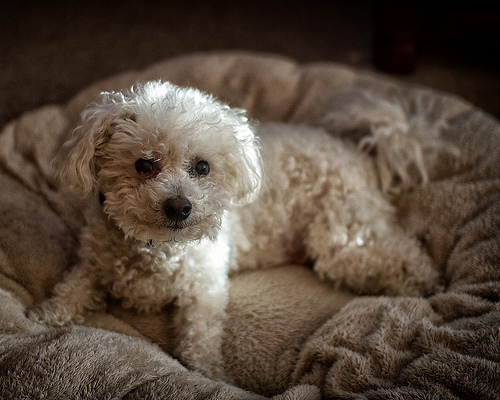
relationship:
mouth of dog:
[127, 176, 225, 226] [26, 79, 460, 384]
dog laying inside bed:
[17, 76, 459, 390] [0, 52, 499, 399]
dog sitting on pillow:
[17, 76, 459, 390] [1, 51, 498, 398]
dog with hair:
[17, 76, 459, 390] [71, 68, 431, 331]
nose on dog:
[161, 190, 198, 227] [17, 76, 459, 390]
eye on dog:
[188, 158, 212, 177] [8, 76, 299, 374]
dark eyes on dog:
[134, 158, 153, 174] [8, 76, 299, 374]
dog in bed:
[26, 79, 460, 384] [8, 52, 494, 389]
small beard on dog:
[141, 230, 210, 249] [26, 79, 460, 384]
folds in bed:
[303, 136, 467, 398] [8, 52, 494, 389]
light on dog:
[143, 78, 262, 290] [17, 76, 459, 390]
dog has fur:
[26, 79, 460, 384] [121, 93, 211, 130]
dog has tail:
[17, 76, 459, 390] [320, 81, 460, 189]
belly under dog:
[220, 238, 296, 278] [17, 76, 459, 390]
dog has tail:
[26, 79, 460, 384] [329, 91, 464, 200]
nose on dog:
[163, 195, 192, 220] [26, 79, 460, 384]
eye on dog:
[195, 160, 210, 175] [17, 76, 459, 390]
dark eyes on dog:
[134, 158, 153, 174] [17, 76, 459, 390]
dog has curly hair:
[17, 76, 459, 390] [48, 79, 266, 209]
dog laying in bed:
[26, 79, 460, 384] [0, 52, 499, 399]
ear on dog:
[43, 72, 125, 184] [27, 84, 295, 374]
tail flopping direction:
[346, 82, 453, 177] [352, 68, 492, 218]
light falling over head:
[152, 82, 259, 303] [62, 80, 260, 245]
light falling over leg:
[152, 82, 259, 303] [174, 245, 229, 380]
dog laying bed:
[26, 79, 460, 384] [8, 52, 494, 389]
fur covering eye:
[138, 147, 158, 162] [130, 155, 158, 177]